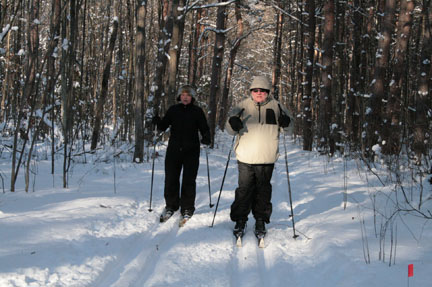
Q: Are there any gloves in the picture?
A: Yes, there are gloves.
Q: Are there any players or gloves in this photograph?
A: Yes, there are gloves.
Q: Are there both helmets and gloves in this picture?
A: No, there are gloves but no helmets.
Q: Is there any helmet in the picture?
A: No, there are no helmets.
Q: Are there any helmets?
A: No, there are no helmets.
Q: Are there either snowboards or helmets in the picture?
A: No, there are no helmets or snowboards.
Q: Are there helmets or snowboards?
A: No, there are no helmets or snowboards.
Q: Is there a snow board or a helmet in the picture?
A: No, there are no helmets or snowboards.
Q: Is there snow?
A: Yes, there is snow.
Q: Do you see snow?
A: Yes, there is snow.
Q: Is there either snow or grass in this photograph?
A: Yes, there is snow.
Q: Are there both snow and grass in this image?
A: No, there is snow but no grass.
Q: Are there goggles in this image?
A: No, there are no goggles.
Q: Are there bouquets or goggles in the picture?
A: No, there are no goggles or bouquets.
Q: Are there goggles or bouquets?
A: No, there are no goggles or bouquets.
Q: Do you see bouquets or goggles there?
A: No, there are no goggles or bouquets.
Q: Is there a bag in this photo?
A: No, there are no bags.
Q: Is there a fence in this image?
A: No, there are no fences.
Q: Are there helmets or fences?
A: No, there are no fences or helmets.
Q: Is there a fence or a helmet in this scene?
A: No, there are no fences or helmets.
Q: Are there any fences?
A: No, there are no fences.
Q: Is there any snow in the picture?
A: Yes, there is snow.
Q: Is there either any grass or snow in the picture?
A: Yes, there is snow.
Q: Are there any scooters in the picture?
A: No, there are no scooters.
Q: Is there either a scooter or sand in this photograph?
A: No, there are no scooters or sand.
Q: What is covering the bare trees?
A: The snow is covering the trees.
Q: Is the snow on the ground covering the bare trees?
A: Yes, the snow is covering the trees.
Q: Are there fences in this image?
A: No, there are no fences.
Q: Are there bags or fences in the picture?
A: No, there are no fences or bags.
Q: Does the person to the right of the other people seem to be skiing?
A: Yes, the person is skiing.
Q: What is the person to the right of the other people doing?
A: The person is skiing.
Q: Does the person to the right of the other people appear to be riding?
A: No, the person is skiing.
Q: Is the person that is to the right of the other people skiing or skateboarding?
A: The person is skiing.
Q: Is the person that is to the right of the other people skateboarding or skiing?
A: The person is skiing.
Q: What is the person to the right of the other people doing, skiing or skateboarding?
A: The person is skiing.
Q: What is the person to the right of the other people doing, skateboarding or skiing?
A: The person is skiing.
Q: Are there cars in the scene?
A: No, there are no cars.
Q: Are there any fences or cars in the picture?
A: No, there are no cars or fences.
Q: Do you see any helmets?
A: No, there are no helmets.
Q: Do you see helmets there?
A: No, there are no helmets.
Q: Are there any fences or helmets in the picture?
A: No, there are no helmets or fences.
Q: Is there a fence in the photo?
A: No, there are no fences.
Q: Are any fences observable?
A: No, there are no fences.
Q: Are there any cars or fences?
A: No, there are no fences or cars.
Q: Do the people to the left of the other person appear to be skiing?
A: Yes, the people are skiing.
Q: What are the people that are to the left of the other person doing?
A: The people are skiing.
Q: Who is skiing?
A: The people are skiing.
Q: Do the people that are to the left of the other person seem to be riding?
A: No, the people are skiing.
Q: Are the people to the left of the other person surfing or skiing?
A: The people are skiing.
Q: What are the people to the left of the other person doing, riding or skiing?
A: The people are skiing.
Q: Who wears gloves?
A: The people wear gloves.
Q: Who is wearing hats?
A: The people are wearing hats.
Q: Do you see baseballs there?
A: No, there are no baseballs.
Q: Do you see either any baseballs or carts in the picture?
A: No, there are no baseballs or carts.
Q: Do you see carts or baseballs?
A: No, there are no baseballs or carts.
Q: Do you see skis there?
A: Yes, there are skis.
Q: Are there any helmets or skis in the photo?
A: Yes, there are skis.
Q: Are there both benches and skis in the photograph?
A: No, there are skis but no benches.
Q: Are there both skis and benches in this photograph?
A: No, there are skis but no benches.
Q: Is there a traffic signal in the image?
A: No, there are no traffic lights.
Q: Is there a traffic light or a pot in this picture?
A: No, there are no traffic lights or pots.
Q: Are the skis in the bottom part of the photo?
A: Yes, the skis are in the bottom of the image.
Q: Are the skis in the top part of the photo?
A: No, the skis are in the bottom of the image.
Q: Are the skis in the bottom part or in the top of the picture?
A: The skis are in the bottom of the image.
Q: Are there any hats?
A: Yes, there is a hat.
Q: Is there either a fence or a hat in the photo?
A: Yes, there is a hat.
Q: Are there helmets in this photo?
A: No, there are no helmets.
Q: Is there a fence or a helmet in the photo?
A: No, there are no helmets or fences.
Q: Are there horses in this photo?
A: No, there are no horses.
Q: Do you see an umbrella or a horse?
A: No, there are no horses or umbrellas.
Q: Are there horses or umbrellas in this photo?
A: No, there are no horses or umbrellas.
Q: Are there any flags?
A: Yes, there is a flag.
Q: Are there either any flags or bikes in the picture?
A: Yes, there is a flag.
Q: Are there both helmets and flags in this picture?
A: No, there is a flag but no helmets.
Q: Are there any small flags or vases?
A: Yes, there is a small flag.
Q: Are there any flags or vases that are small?
A: Yes, the flag is small.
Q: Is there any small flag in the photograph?
A: Yes, there is a small flag.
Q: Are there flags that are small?
A: Yes, there is a flag that is small.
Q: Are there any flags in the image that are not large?
A: Yes, there is a small flag.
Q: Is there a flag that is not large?
A: Yes, there is a small flag.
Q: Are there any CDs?
A: No, there are no cds.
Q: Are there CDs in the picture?
A: No, there are no cds.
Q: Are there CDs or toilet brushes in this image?
A: No, there are no CDs or toilet brushes.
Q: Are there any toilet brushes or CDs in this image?
A: No, there are no CDs or toilet brushes.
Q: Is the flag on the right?
A: Yes, the flag is on the right of the image.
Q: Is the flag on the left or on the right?
A: The flag is on the right of the image.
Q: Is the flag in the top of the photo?
A: No, the flag is in the bottom of the image.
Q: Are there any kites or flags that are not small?
A: No, there is a flag but it is small.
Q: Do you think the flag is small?
A: Yes, the flag is small.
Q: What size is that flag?
A: The flag is small.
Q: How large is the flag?
A: The flag is small.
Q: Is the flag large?
A: No, the flag is small.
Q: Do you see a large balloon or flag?
A: No, there is a flag but it is small.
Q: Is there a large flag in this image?
A: No, there is a flag but it is small.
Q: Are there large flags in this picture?
A: No, there is a flag but it is small.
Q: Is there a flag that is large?
A: No, there is a flag but it is small.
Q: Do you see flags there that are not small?
A: No, there is a flag but it is small.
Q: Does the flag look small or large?
A: The flag is small.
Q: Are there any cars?
A: No, there are no cars.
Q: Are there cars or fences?
A: No, there are no cars or fences.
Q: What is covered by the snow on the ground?
A: The trees are covered by the snow.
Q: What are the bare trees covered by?
A: The trees are covered by the snow.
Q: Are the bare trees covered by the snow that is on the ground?
A: Yes, the trees are covered by the snow.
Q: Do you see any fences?
A: No, there are no fences.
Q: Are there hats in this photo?
A: Yes, there is a hat.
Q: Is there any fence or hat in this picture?
A: Yes, there is a hat.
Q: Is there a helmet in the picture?
A: No, there are no helmets.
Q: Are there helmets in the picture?
A: No, there are no helmets.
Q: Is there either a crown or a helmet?
A: No, there are no helmets or crowns.